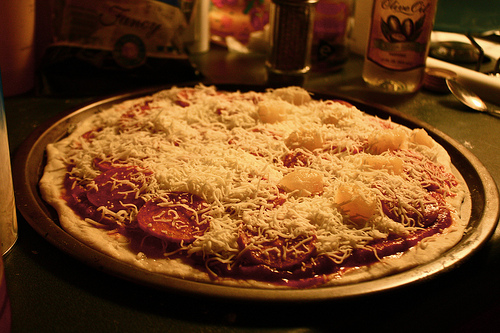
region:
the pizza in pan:
[50, 82, 470, 276]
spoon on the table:
[443, 73, 498, 109]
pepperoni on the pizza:
[131, 193, 203, 249]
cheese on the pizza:
[172, 117, 271, 215]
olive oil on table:
[369, 1, 429, 90]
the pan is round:
[19, 72, 491, 309]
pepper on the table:
[259, 3, 319, 76]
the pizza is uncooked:
[62, 78, 484, 279]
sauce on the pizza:
[276, 271, 331, 278]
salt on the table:
[191, 3, 218, 51]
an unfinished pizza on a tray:
[15, 23, 492, 324]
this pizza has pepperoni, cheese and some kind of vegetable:
[71, 77, 478, 274]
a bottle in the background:
[356, 1, 432, 101]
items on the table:
[18, 3, 345, 79]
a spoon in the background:
[439, 72, 494, 120]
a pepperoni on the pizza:
[131, 193, 217, 254]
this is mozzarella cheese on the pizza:
[152, 124, 269, 206]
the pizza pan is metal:
[21, 100, 183, 316]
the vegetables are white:
[256, 88, 415, 237]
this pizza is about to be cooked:
[24, 62, 472, 288]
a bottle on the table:
[360, 0, 435, 95]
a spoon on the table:
[442, 77, 494, 119]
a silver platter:
[25, 75, 490, 300]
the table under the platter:
[380, 295, 491, 316]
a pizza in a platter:
[33, 80, 476, 298]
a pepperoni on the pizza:
[135, 190, 195, 228]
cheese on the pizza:
[176, 163, 246, 208]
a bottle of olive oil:
[363, 2, 418, 77]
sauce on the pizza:
[353, 233, 407, 250]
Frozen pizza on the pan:
[40, 85, 472, 287]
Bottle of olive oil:
[359, 0, 439, 92]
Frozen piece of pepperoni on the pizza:
[138, 185, 209, 243]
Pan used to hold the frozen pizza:
[23, 83, 499, 298]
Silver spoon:
[443, 75, 499, 121]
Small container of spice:
[264, 0, 315, 77]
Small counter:
[8, 48, 499, 242]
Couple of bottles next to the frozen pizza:
[311, 0, 438, 97]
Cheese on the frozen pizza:
[64, 84, 456, 280]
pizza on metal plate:
[41, 82, 468, 288]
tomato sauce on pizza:
[343, 194, 451, 257]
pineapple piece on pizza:
[278, 169, 323, 193]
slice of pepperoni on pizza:
[138, 199, 204, 242]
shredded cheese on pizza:
[156, 142, 273, 204]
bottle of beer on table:
[364, 1, 436, 92]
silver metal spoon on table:
[447, 77, 499, 122]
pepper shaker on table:
[266, 4, 313, 76]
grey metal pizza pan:
[21, 81, 496, 303]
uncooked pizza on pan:
[40, 82, 473, 288]